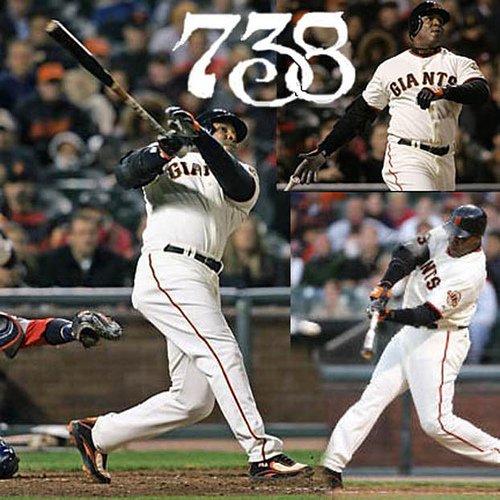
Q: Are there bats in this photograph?
A: Yes, there is a bat.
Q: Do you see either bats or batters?
A: Yes, there is a bat.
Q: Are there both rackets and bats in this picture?
A: No, there is a bat but no rackets.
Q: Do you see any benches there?
A: No, there are no benches.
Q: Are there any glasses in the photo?
A: No, there are no glasses.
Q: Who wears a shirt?
A: The man wears a shirt.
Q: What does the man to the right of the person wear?
A: The man wears a shirt.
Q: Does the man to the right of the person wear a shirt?
A: Yes, the man wears a shirt.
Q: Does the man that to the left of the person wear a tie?
A: No, the man wears a shirt.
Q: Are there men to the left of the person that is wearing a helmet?
A: Yes, there is a man to the left of the person.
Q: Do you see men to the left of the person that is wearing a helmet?
A: Yes, there is a man to the left of the person.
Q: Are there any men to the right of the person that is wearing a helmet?
A: No, the man is to the left of the person.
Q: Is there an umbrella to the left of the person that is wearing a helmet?
A: No, there is a man to the left of the person.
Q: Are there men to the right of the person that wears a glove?
A: Yes, there is a man to the right of the person.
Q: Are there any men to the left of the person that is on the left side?
A: No, the man is to the right of the person.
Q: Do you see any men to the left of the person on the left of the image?
A: No, the man is to the right of the person.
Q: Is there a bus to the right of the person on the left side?
A: No, there is a man to the right of the person.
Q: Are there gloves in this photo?
A: Yes, there are gloves.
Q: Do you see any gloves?
A: Yes, there are gloves.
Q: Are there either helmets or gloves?
A: Yes, there are gloves.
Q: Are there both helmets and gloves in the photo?
A: Yes, there are both gloves and a helmet.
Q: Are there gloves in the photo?
A: Yes, there are gloves.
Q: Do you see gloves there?
A: Yes, there are gloves.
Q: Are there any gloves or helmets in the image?
A: Yes, there are gloves.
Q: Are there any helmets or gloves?
A: Yes, there are gloves.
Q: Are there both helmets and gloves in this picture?
A: Yes, there are both gloves and a helmet.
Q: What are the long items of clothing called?
A: The clothing items are pants.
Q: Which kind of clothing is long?
A: The clothing is pants.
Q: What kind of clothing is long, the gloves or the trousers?
A: The trousers are long.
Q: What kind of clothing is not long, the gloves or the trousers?
A: The gloves are not long.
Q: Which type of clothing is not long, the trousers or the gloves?
A: The gloves are not long.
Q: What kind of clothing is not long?
A: The clothing is gloves.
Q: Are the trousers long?
A: Yes, the trousers are long.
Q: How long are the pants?
A: The pants are long.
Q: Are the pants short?
A: No, the pants are long.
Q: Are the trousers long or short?
A: The trousers are long.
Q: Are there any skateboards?
A: No, there are no skateboards.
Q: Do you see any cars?
A: No, there are no cars.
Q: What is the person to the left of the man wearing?
A: The person is wearing a glove.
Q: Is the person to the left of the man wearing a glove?
A: Yes, the person is wearing a glove.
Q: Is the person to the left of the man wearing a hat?
A: No, the person is wearing a glove.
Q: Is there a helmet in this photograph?
A: Yes, there is a helmet.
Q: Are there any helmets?
A: Yes, there is a helmet.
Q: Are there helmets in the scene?
A: Yes, there is a helmet.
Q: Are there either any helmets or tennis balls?
A: Yes, there is a helmet.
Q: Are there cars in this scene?
A: No, there are no cars.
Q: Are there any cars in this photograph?
A: No, there are no cars.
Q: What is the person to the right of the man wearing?
A: The person is wearing a helmet.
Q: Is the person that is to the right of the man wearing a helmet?
A: Yes, the person is wearing a helmet.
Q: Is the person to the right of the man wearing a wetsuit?
A: No, the person is wearing a helmet.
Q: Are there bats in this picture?
A: Yes, there is a bat.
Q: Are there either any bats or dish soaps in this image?
A: Yes, there is a bat.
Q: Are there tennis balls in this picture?
A: No, there are no tennis balls.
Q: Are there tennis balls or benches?
A: No, there are no tennis balls or benches.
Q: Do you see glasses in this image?
A: No, there are no glasses.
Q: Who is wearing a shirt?
A: The man is wearing a shirt.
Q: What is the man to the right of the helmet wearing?
A: The man is wearing a shirt.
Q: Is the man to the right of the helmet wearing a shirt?
A: Yes, the man is wearing a shirt.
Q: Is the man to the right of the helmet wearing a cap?
A: No, the man is wearing a shirt.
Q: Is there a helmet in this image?
A: Yes, there is a helmet.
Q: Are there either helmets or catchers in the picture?
A: Yes, there is a helmet.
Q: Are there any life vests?
A: No, there are no life vests.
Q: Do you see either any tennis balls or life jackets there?
A: No, there are no life jackets or tennis balls.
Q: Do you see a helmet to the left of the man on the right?
A: Yes, there is a helmet to the left of the man.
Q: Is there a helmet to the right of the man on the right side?
A: No, the helmet is to the left of the man.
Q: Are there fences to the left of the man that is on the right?
A: No, there is a helmet to the left of the man.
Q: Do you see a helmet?
A: Yes, there is a helmet.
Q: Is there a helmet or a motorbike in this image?
A: Yes, there is a helmet.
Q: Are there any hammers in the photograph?
A: No, there are no hammers.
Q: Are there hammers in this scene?
A: No, there are no hammers.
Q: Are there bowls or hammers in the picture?
A: No, there are no hammers or bowls.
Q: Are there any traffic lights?
A: No, there are no traffic lights.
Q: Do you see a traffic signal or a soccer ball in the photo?
A: No, there are no traffic lights or soccer balls.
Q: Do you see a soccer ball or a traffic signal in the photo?
A: No, there are no traffic lights or soccer balls.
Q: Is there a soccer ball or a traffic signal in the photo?
A: No, there are no traffic lights or soccer balls.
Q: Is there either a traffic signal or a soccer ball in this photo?
A: No, there are no traffic lights or soccer balls.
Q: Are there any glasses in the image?
A: No, there are no glasses.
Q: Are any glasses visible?
A: No, there are no glasses.